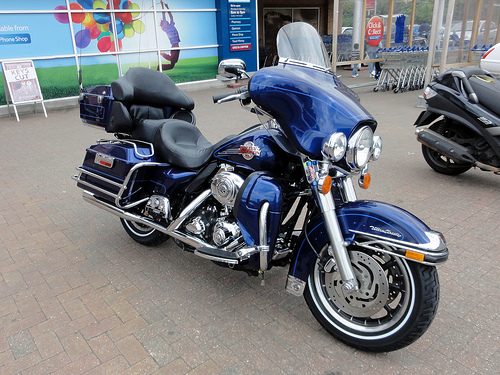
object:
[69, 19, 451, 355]
motorcycle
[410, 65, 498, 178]
motorcycle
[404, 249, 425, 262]
reflectors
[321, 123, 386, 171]
headlights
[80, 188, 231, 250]
tailpipe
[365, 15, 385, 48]
sticker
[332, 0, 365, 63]
window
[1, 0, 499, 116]
store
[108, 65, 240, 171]
seat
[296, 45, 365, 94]
carts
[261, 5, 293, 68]
doors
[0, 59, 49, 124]
sign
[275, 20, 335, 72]
windshield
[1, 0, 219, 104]
picture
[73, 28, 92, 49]
balloons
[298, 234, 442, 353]
tire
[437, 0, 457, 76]
pole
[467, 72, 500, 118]
seat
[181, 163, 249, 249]
engine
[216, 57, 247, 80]
mirror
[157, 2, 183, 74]
woman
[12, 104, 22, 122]
legs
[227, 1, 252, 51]
sign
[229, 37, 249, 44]
list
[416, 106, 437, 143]
car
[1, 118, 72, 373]
road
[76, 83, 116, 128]
back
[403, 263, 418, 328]
edge